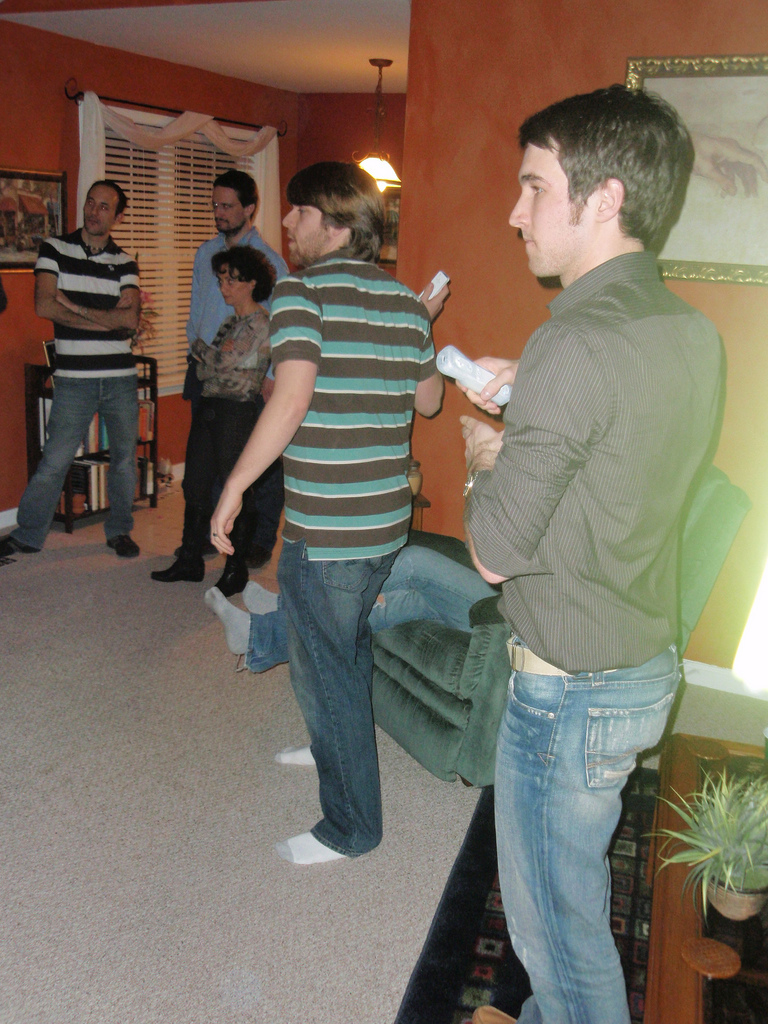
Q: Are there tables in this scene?
A: Yes, there is a table.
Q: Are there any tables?
A: Yes, there is a table.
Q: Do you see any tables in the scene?
A: Yes, there is a table.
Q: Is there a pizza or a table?
A: Yes, there is a table.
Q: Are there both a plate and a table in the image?
A: No, there is a table but no plates.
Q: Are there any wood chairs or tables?
A: Yes, there is a wood table.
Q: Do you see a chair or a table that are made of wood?
A: Yes, the table is made of wood.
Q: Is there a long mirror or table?
A: Yes, there is a long table.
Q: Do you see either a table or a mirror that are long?
A: Yes, the table is long.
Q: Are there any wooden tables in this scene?
A: Yes, there is a wood table.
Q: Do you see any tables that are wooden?
A: Yes, there is a wood table.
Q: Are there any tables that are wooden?
A: Yes, there is a table that is wooden.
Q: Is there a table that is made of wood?
A: Yes, there is a table that is made of wood.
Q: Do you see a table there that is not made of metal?
A: Yes, there is a table that is made of wood.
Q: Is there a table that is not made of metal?
A: Yes, there is a table that is made of wood.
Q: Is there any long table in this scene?
A: Yes, there is a long table.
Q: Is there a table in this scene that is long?
A: Yes, there is a table that is long.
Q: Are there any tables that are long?
A: Yes, there is a table that is long.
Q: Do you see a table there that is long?
A: Yes, there is a table that is long.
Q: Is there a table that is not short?
A: Yes, there is a long table.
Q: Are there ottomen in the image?
A: No, there are no ottomen.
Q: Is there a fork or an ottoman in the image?
A: No, there are no ottomen or forks.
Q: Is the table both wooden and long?
A: Yes, the table is wooden and long.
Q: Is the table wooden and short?
A: No, the table is wooden but long.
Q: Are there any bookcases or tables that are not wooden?
A: No, there is a table but it is wooden.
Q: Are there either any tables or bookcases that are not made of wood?
A: No, there is a table but it is made of wood.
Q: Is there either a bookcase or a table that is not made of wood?
A: No, there is a table but it is made of wood.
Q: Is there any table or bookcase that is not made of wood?
A: No, there is a table but it is made of wood.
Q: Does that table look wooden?
A: Yes, the table is wooden.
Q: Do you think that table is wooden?
A: Yes, the table is wooden.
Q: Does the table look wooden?
A: Yes, the table is wooden.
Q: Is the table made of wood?
A: Yes, the table is made of wood.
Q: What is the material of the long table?
A: The table is made of wood.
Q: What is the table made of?
A: The table is made of wood.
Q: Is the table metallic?
A: No, the table is wooden.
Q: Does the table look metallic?
A: No, the table is wooden.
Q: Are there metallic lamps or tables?
A: No, there is a table but it is wooden.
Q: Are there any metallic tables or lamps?
A: No, there is a table but it is wooden.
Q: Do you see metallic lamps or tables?
A: No, there is a table but it is wooden.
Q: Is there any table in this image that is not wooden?
A: No, there is a table but it is wooden.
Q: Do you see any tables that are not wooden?
A: No, there is a table but it is wooden.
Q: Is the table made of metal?
A: No, the table is made of wood.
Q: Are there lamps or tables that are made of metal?
A: No, there is a table but it is made of wood.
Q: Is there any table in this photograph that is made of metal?
A: No, there is a table but it is made of wood.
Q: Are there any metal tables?
A: No, there is a table but it is made of wood.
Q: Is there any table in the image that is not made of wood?
A: No, there is a table but it is made of wood.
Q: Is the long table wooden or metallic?
A: The table is wooden.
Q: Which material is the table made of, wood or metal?
A: The table is made of wood.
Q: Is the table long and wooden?
A: Yes, the table is long and wooden.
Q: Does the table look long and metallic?
A: No, the table is long but wooden.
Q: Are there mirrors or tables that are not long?
A: No, there is a table but it is long.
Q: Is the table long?
A: Yes, the table is long.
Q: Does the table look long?
A: Yes, the table is long.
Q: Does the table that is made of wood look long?
A: Yes, the table is long.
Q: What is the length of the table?
A: The table is long.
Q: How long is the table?
A: The table is long.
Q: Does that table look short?
A: No, the table is long.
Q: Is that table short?
A: No, the table is long.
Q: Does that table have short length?
A: No, the table is long.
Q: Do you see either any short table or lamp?
A: No, there is a table but it is long.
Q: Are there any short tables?
A: No, there is a table but it is long.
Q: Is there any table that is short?
A: No, there is a table but it is long.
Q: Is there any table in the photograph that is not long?
A: No, there is a table but it is long.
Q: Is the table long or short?
A: The table is long.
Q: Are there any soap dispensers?
A: No, there are no soap dispensers.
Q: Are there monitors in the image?
A: No, there are no monitors.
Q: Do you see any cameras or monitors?
A: No, there are no monitors or cameras.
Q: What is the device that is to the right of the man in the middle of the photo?
A: The device is a controller.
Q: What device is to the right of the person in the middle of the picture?
A: The device is a controller.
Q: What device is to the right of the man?
A: The device is a controller.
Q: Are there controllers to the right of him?
A: Yes, there is a controller to the right of the man.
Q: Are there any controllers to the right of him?
A: Yes, there is a controller to the right of the man.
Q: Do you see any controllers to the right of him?
A: Yes, there is a controller to the right of the man.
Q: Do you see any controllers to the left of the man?
A: No, the controller is to the right of the man.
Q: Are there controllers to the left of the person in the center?
A: No, the controller is to the right of the man.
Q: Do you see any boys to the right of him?
A: No, there is a controller to the right of the man.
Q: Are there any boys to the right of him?
A: No, there is a controller to the right of the man.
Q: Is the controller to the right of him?
A: Yes, the controller is to the right of a man.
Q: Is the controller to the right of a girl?
A: No, the controller is to the right of a man.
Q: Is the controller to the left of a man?
A: No, the controller is to the right of a man.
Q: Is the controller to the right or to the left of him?
A: The controller is to the right of the man.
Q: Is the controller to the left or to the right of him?
A: The controller is to the right of the man.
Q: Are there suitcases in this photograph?
A: No, there are no suitcases.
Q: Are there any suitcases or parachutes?
A: No, there are no suitcases or parachutes.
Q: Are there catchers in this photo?
A: No, there are no catchers.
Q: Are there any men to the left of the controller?
A: Yes, there is a man to the left of the controller.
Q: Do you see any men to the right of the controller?
A: No, the man is to the left of the controller.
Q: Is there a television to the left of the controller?
A: No, there is a man to the left of the controller.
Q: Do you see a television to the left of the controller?
A: No, there is a man to the left of the controller.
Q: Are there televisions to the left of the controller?
A: No, there is a man to the left of the controller.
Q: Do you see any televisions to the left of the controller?
A: No, there is a man to the left of the controller.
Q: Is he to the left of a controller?
A: Yes, the man is to the left of a controller.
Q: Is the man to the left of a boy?
A: No, the man is to the left of a controller.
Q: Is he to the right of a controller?
A: No, the man is to the left of a controller.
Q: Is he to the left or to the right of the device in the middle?
A: The man is to the left of the controller.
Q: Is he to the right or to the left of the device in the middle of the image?
A: The man is to the left of the controller.